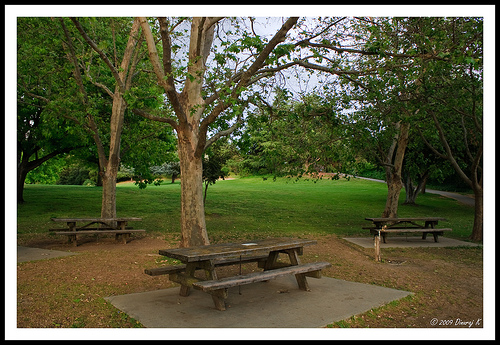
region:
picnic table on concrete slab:
[101, 230, 418, 325]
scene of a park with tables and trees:
[21, 16, 485, 328]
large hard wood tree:
[135, 15, 312, 245]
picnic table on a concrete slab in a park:
[362, 209, 457, 252]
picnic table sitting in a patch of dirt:
[45, 202, 152, 247]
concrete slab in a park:
[13, 239, 85, 278]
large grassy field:
[15, 175, 483, 232]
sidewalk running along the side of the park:
[315, 155, 485, 202]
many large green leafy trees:
[17, 19, 482, 248]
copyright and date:
[424, 314, 481, 326]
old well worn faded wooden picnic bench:
[143, 230, 326, 310]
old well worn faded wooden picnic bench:
[48, 212, 144, 242]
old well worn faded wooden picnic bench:
[364, 209, 450, 241]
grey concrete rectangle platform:
[100, 265, 407, 327]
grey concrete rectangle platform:
[17, 243, 72, 268]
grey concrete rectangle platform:
[347, 225, 477, 250]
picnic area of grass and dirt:
[17, 231, 477, 324]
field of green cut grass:
[20, 170, 467, 240]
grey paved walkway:
[332, 162, 479, 215]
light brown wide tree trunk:
[163, 54, 216, 245]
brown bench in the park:
[138, 237, 339, 303]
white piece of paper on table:
[239, 235, 257, 255]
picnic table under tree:
[164, 235, 318, 263]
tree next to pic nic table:
[139, 25, 236, 247]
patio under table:
[351, 228, 485, 270]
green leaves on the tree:
[171, 54, 260, 136]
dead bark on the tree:
[178, 128, 222, 252]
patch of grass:
[221, 177, 363, 238]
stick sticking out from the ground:
[371, 222, 398, 267]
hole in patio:
[271, 285, 313, 306]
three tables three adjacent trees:
[38, 178, 453, 311]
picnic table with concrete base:
[101, 232, 416, 342]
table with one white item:
[135, 229, 337, 318]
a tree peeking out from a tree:
[179, 24, 231, 243]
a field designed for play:
[208, 176, 363, 218]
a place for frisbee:
[208, 176, 384, 219]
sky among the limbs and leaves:
[139, 16, 485, 156]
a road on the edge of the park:
[316, 118, 488, 303]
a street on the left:
[323, 137, 490, 220]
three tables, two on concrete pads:
[18, 201, 498, 335]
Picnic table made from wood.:
[118, 233, 375, 320]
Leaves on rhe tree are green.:
[23, 20, 173, 192]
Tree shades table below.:
[345, 27, 489, 264]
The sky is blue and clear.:
[152, 9, 388, 136]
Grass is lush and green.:
[38, 167, 430, 231]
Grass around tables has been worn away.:
[35, 210, 422, 301]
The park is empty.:
[31, 200, 479, 318]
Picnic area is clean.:
[32, 177, 486, 328]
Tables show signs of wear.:
[39, 197, 459, 311]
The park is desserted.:
[20, 11, 485, 326]